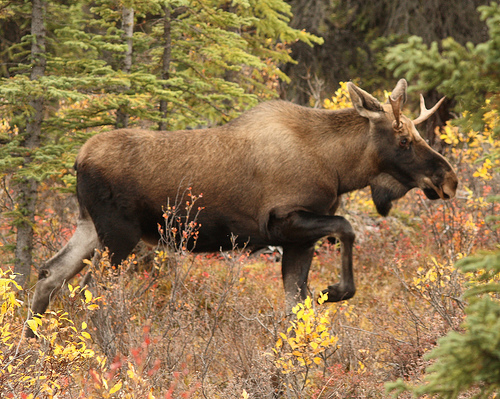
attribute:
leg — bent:
[276, 209, 359, 304]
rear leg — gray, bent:
[9, 217, 86, 349]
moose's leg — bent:
[299, 212, 367, 301]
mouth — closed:
[418, 170, 450, 202]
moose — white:
[4, 79, 477, 379]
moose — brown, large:
[23, 82, 455, 337]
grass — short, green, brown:
[387, 274, 444, 330]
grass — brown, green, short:
[214, 255, 280, 305]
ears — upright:
[352, 80, 414, 125]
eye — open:
[399, 131, 414, 149]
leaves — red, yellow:
[0, 185, 444, 397]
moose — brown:
[17, 75, 462, 351]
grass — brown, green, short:
[335, 310, 445, 397]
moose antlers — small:
[378, 70, 449, 132]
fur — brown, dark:
[281, 127, 409, 177]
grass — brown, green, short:
[15, 186, 499, 391]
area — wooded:
[1, 40, 482, 395]